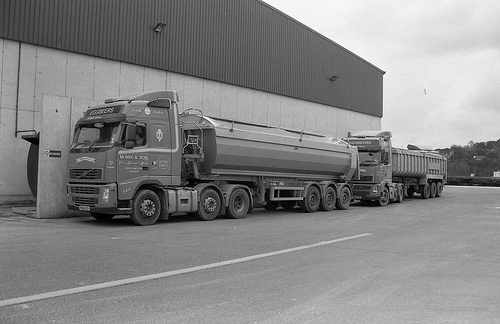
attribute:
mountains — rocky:
[434, 141, 498, 188]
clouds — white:
[283, 0, 497, 145]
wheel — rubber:
[422, 183, 429, 198]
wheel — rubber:
[229, 188, 251, 218]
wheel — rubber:
[430, 181, 439, 195]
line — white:
[66, 232, 299, 302]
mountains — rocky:
[445, 136, 497, 177]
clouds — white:
[389, 1, 498, 134]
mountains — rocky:
[416, 132, 498, 179]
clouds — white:
[411, 102, 462, 131]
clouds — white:
[384, 128, 433, 147]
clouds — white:
[452, 110, 499, 129]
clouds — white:
[427, 136, 469, 150]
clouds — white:
[382, 50, 498, 104]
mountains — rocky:
[453, 144, 499, 174]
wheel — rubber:
[129, 186, 162, 226]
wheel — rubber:
[377, 186, 392, 206]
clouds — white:
[266, 0, 499, 151]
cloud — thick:
[262, 0, 499, 150]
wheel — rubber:
[337, 178, 364, 214]